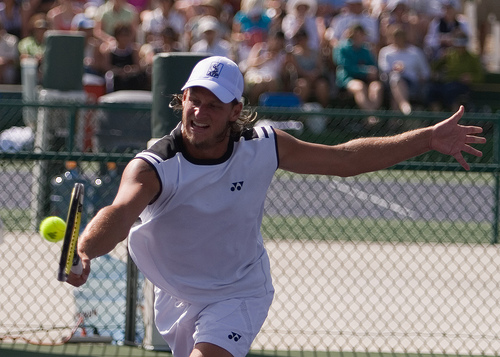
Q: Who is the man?
A: A tennis player.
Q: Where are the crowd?
A: Behind the player.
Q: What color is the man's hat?
A: White.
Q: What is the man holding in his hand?
A: A tennis racket.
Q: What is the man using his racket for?
A: To hit the ball.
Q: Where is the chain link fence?
A: Behind the player.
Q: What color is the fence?
A: Green.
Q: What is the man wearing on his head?
A: A hat.